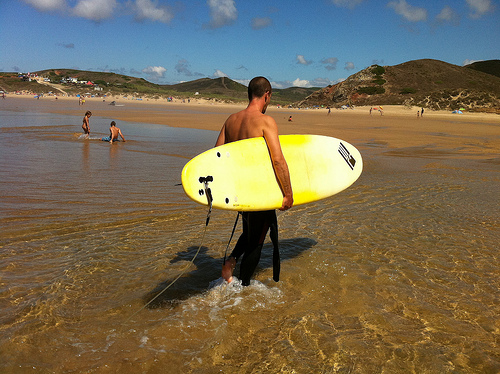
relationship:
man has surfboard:
[214, 76, 294, 285] [176, 133, 365, 213]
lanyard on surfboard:
[125, 176, 218, 335] [176, 133, 365, 213]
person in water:
[94, 121, 130, 145] [3, 111, 499, 370]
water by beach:
[3, 111, 499, 370] [0, 90, 500, 161]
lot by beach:
[23, 71, 96, 87] [0, 90, 500, 161]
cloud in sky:
[129, 0, 176, 30] [0, 1, 499, 91]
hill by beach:
[307, 57, 499, 104] [0, 90, 500, 161]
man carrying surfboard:
[214, 76, 294, 285] [176, 133, 365, 213]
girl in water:
[82, 110, 92, 135] [3, 111, 499, 370]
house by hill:
[84, 76, 94, 87] [307, 57, 499, 104]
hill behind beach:
[307, 57, 499, 104] [0, 90, 500, 161]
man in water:
[214, 76, 294, 285] [3, 111, 499, 370]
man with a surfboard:
[214, 76, 294, 285] [176, 133, 365, 213]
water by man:
[3, 111, 499, 370] [214, 76, 294, 285]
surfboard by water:
[176, 133, 365, 213] [3, 111, 499, 370]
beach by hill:
[0, 90, 500, 161] [307, 57, 499, 104]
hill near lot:
[307, 57, 499, 104] [23, 71, 96, 87]